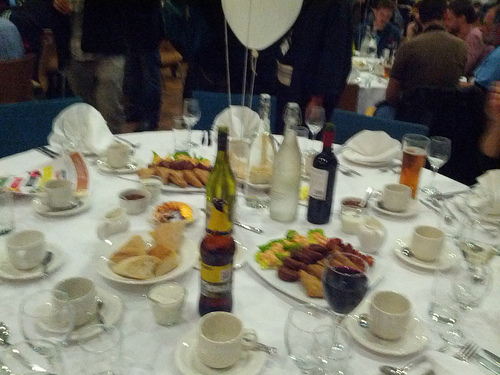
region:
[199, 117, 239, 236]
a bottle of alcohol on a table.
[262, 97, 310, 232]
a clear bottle on a table.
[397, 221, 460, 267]
a cup on a small plate.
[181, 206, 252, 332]
a bottle of liquid.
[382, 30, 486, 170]
a chair sitting at a table.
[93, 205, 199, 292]
a plate with food on it.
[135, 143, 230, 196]
a plate of food on a table.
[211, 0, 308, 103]
a white balloon at a table.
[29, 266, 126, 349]
a plate with a cup on it.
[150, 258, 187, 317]
a small container.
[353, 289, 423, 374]
white cup and saucer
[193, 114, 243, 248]
green bottle of wine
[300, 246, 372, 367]
a glass of red wine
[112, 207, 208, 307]
white plate with baked goods on it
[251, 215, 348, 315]
plate with food on it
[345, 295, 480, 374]
silver and white dishes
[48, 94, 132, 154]
white napkin on table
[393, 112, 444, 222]
a tall glass of beer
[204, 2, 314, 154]
white balloon and string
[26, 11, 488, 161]
people at a party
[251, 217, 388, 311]
The table have food on it.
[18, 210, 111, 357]
Cups and saucers on the table.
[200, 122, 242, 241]
A bottle of wine of the table.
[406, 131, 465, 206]
A glass of wine sitting of the table.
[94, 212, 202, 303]
Pieces of bread in a white plate.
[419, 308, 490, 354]
The silverware is next to the wine glasses.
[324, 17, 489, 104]
People sitting at another table in the background.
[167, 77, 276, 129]
The blue chair are pushed in at the table.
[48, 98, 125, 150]
White napkins is laying on the table.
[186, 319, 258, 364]
The teacup are empty.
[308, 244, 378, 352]
A glass of red wine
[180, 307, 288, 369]
a white coffee mug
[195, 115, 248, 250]
a bottle of white wine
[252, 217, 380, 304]
Here is a plate full of food.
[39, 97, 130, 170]
This is a white decorative napkin.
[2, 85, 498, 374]
This is a full table.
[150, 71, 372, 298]
Five wine bottles on the table.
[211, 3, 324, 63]
A white balloon is in the air.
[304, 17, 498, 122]
People are eating at a table.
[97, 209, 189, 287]
A bowl of chips are on the table.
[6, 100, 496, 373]
A table with food and drinks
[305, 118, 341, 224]
A bottle of red wine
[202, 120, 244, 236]
A bottle of white wine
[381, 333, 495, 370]
Various pieces of silverware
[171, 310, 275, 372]
A cup and saucer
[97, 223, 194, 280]
Pieces of bread in a dish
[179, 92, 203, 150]
A wine glass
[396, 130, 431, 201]
A glass of beer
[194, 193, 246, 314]
A beer bottle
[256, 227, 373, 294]
This is a plate of food